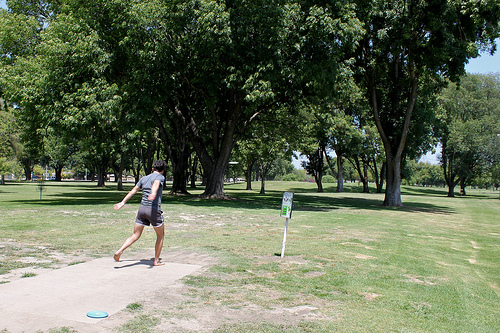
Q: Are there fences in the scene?
A: No, there are no fences.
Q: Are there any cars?
A: No, there are no cars.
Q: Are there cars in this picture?
A: No, there are no cars.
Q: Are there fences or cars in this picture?
A: No, there are no cars or fences.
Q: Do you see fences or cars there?
A: No, there are no cars or fences.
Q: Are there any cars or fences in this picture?
A: No, there are no cars or fences.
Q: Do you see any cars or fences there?
A: No, there are no cars or fences.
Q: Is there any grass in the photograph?
A: Yes, there is grass.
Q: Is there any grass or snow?
A: Yes, there is grass.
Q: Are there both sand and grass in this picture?
A: No, there is grass but no sand.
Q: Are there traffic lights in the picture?
A: No, there are no traffic lights.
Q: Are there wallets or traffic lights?
A: No, there are no traffic lights or wallets.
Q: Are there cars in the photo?
A: No, there are no cars.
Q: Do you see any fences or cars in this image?
A: No, there are no cars or fences.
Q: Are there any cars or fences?
A: No, there are no cars or fences.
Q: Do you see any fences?
A: No, there are no fences.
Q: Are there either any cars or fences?
A: No, there are no fences or cars.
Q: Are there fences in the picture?
A: No, there are no fences.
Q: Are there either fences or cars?
A: No, there are no fences or cars.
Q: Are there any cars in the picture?
A: No, there are no cars.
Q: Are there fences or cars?
A: No, there are no cars or fences.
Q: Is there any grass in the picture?
A: Yes, there is grass.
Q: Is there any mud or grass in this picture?
A: Yes, there is grass.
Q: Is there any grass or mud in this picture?
A: Yes, there is grass.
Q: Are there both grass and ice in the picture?
A: No, there is grass but no ice.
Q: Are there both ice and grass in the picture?
A: No, there is grass but no ice.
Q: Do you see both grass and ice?
A: No, there is grass but no ice.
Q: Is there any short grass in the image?
A: Yes, there is short grass.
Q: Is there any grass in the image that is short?
A: Yes, there is grass that is short.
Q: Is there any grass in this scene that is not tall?
A: Yes, there is short grass.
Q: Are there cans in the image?
A: No, there are no cans.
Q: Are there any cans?
A: No, there are no cans.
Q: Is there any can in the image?
A: No, there are no cans.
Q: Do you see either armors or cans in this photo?
A: No, there are no cans or armors.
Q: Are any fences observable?
A: No, there are no fences.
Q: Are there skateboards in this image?
A: No, there are no skateboards.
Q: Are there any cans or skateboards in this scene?
A: No, there are no skateboards or cans.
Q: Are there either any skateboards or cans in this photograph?
A: No, there are no skateboards or cans.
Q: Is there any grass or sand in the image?
A: Yes, there is grass.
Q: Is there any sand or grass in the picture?
A: Yes, there is grass.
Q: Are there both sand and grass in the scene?
A: No, there is grass but no sand.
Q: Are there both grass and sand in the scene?
A: No, there is grass but no sand.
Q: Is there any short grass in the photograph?
A: Yes, there is short grass.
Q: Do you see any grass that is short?
A: Yes, there is short grass.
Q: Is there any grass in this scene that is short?
A: Yes, there is grass that is short.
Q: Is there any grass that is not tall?
A: Yes, there is short grass.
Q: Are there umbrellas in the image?
A: No, there are no umbrellas.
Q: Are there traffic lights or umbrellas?
A: No, there are no umbrellas or traffic lights.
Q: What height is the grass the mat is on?
A: The grass is short.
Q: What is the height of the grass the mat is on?
A: The grass is short.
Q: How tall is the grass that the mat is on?
A: The grass is short.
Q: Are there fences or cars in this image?
A: No, there are no cars or fences.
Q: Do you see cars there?
A: No, there are no cars.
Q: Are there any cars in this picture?
A: No, there are no cars.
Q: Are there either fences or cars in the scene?
A: No, there are no cars or fences.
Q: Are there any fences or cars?
A: No, there are no fences or cars.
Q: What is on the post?
A: The sign is on the post.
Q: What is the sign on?
A: The sign is on the post.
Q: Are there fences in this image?
A: No, there are no fences.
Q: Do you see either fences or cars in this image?
A: No, there are no fences or cars.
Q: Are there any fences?
A: No, there are no fences.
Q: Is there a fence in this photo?
A: No, there are no fences.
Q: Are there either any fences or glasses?
A: No, there are no fences or glasses.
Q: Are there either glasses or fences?
A: No, there are no fences or glasses.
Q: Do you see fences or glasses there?
A: No, there are no fences or glasses.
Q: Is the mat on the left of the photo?
A: Yes, the mat is on the left of the image.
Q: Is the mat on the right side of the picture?
A: No, the mat is on the left of the image.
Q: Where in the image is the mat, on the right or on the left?
A: The mat is on the left of the image.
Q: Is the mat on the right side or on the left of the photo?
A: The mat is on the left of the image.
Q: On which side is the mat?
A: The mat is on the left of the image.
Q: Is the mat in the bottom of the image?
A: Yes, the mat is in the bottom of the image.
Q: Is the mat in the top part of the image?
A: No, the mat is in the bottom of the image.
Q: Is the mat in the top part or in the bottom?
A: The mat is in the bottom of the image.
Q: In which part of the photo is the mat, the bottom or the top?
A: The mat is in the bottom of the image.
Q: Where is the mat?
A: The mat is on the grass.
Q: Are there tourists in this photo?
A: No, there are no tourists.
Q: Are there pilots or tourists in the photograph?
A: No, there are no tourists or pilots.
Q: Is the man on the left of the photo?
A: Yes, the man is on the left of the image.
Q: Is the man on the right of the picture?
A: No, the man is on the left of the image.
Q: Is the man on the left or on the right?
A: The man is on the left of the image.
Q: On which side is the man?
A: The man is on the left of the image.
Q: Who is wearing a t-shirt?
A: The man is wearing a t-shirt.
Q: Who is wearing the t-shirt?
A: The man is wearing a t-shirt.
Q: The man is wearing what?
A: The man is wearing a t-shirt.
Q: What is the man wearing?
A: The man is wearing a t-shirt.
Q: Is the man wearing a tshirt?
A: Yes, the man is wearing a tshirt.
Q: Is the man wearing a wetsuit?
A: No, the man is wearing a tshirt.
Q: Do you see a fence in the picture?
A: No, there are no fences.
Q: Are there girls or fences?
A: No, there are no fences or girls.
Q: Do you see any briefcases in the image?
A: No, there are no briefcases.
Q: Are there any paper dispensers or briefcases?
A: No, there are no briefcases or paper dispensers.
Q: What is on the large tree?
A: The trunk is on the tree.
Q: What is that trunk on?
A: The trunk is on the tree.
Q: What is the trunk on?
A: The trunk is on the tree.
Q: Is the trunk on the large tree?
A: Yes, the trunk is on the tree.